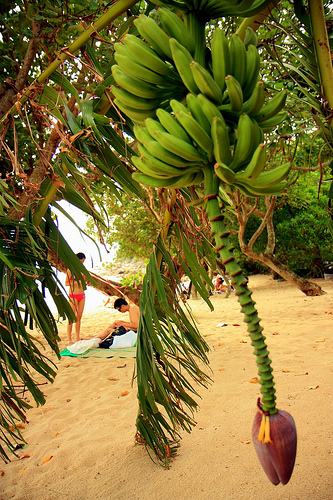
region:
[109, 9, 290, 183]
green bananas on tree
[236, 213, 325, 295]
trunk of bent tree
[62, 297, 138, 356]
man sitting on blanket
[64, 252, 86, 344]
woman in red bikini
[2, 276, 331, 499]
sandy surface of beach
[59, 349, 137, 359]
sand on green blanket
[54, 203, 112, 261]
light of daytime sky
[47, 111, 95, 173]
dried brown tree leaves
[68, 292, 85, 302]
red bottoms of bikini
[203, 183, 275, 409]
green vine of banana tree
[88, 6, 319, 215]
Unripe bananas are on the tree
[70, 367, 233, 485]
There is sand on teh beach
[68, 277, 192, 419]
A man is sitting on the blanket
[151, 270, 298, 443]
The leaves on the tree are green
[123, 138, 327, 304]
The bananas are green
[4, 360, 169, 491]
Dead leaves are on the ground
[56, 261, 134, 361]
The woman is wearing a red bikini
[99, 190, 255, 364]
The trees are in the background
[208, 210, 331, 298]
The tree has a brown trunk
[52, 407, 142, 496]
The sand is brown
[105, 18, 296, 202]
The bananas on the tree.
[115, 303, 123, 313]
The sunglasses the guy is wearing.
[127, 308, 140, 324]
The back of the guy.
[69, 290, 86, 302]
The bikini bottoms of the girl.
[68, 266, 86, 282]
The bikini top the girl is wearing.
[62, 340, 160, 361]
The green towel on the sand.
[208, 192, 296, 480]
The purple fruit hanging off of the banana tree.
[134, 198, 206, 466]
The big banana leaf.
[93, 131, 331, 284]
The trees in the background.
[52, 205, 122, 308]
The bright clear sky in the background.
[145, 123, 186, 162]
Green banana in a tree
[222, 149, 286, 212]
Green banana in a tree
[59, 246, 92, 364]
Girl standing in the sand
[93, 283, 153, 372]
Man sitting in the sand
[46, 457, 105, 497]
Small groves in the sand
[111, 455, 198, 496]
Small groves in the sand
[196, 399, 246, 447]
Small groves in the sand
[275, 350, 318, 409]
Small groves in the sand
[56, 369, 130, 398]
Small groves in the sand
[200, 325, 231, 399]
Small groves in the sand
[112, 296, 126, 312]
Person has dark hair.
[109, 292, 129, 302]
Person has short hair.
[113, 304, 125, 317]
Sunglasses on man's face.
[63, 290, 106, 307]
Girl wearing red bikini bottoms.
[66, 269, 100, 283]
Person wearing red bikini top.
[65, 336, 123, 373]
Blue towel sitting on sand.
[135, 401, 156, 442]
Green leaves on tree.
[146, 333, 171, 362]
Green leaves on tree.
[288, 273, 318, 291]
Palm tree sticking out of the sand.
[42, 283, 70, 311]
Green leaves on tree.